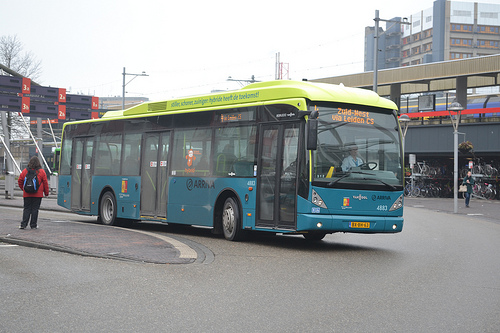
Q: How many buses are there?
A: 1.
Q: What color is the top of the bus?
A: Yellow.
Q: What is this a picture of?
A: Bus.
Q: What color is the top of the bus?
A: Yellow.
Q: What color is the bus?
A: Blue.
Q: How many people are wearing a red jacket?
A: 1.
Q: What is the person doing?
A: Standing.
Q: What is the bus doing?
A: Turning.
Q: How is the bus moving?
A: The driver is driving it.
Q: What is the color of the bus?
A: Blue.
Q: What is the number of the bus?
A: 4883.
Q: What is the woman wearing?
A: A red jacket and a black jeans.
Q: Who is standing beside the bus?
A: A woman.